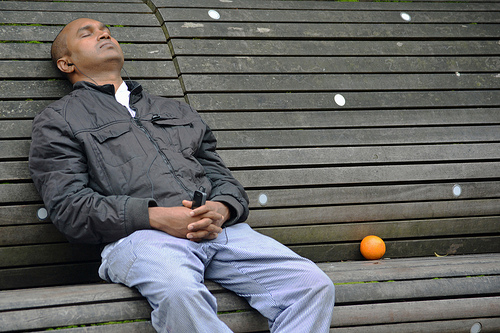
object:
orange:
[360, 235, 385, 260]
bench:
[1, 1, 497, 333]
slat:
[171, 23, 499, 38]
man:
[25, 16, 335, 332]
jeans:
[97, 223, 337, 332]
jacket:
[30, 79, 248, 245]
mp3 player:
[187, 186, 207, 218]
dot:
[333, 91, 350, 108]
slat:
[187, 91, 500, 106]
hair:
[53, 30, 69, 58]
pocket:
[91, 120, 149, 168]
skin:
[149, 198, 231, 242]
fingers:
[180, 230, 214, 238]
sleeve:
[30, 104, 162, 248]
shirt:
[113, 78, 137, 120]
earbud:
[67, 60, 75, 68]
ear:
[54, 57, 75, 74]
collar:
[68, 76, 145, 101]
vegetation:
[7, 21, 46, 29]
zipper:
[141, 116, 194, 202]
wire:
[66, 52, 201, 205]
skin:
[70, 16, 105, 66]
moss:
[4, 36, 44, 45]